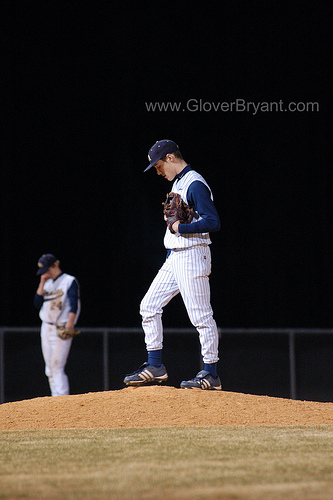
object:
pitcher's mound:
[2, 380, 332, 424]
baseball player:
[35, 255, 81, 393]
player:
[32, 251, 80, 396]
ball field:
[2, 315, 328, 497]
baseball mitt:
[158, 193, 193, 234]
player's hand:
[163, 215, 182, 236]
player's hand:
[60, 312, 78, 334]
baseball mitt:
[54, 318, 76, 339]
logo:
[197, 377, 216, 390]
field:
[5, 425, 331, 497]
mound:
[0, 383, 332, 498]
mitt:
[155, 187, 194, 238]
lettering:
[134, 93, 324, 124]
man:
[130, 134, 235, 385]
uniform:
[136, 166, 232, 383]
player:
[133, 129, 243, 393]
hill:
[52, 389, 328, 428]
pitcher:
[120, 138, 223, 391]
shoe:
[180, 372, 224, 390]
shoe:
[124, 363, 169, 389]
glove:
[143, 186, 191, 240]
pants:
[138, 247, 230, 357]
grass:
[11, 426, 325, 489]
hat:
[141, 135, 179, 174]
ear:
[165, 150, 174, 161]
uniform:
[140, 168, 221, 367]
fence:
[1, 328, 332, 399]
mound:
[0, 384, 332, 428]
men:
[32, 252, 96, 405]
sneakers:
[122, 364, 222, 387]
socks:
[140, 343, 219, 382]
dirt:
[2, 387, 329, 423]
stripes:
[139, 368, 153, 381]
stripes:
[196, 377, 211, 387]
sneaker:
[121, 363, 168, 384]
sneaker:
[178, 369, 222, 389]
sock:
[144, 350, 162, 366]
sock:
[198, 357, 221, 379]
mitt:
[54, 326, 73, 338]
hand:
[60, 326, 73, 338]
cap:
[37, 251, 62, 274]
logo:
[137, 370, 155, 383]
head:
[36, 254, 60, 277]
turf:
[0, 422, 329, 498]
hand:
[162, 207, 177, 233]